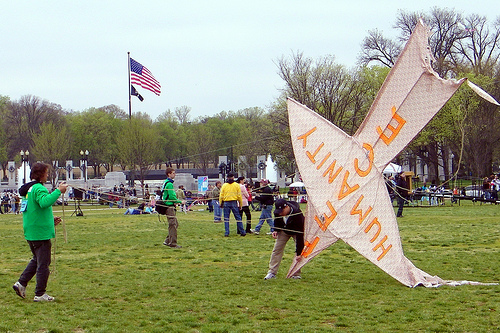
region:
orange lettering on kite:
[298, 125, 404, 267]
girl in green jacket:
[15, 180, 62, 242]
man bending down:
[259, 193, 305, 270]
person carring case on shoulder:
[153, 172, 173, 217]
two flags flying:
[113, 75, 174, 100]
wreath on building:
[254, 150, 265, 177]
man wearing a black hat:
[270, 188, 291, 216]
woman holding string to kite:
[14, 165, 325, 295]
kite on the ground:
[281, 23, 426, 313]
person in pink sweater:
[240, 175, 257, 231]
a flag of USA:
[104, 50, 219, 120]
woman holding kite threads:
[12, 128, 128, 289]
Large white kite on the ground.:
[266, 23, 466, 290]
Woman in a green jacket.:
[15, 155, 62, 305]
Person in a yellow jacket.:
[215, 171, 245, 236]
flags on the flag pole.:
[122, 49, 161, 106]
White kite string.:
[64, 135, 320, 239]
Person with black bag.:
[155, 165, 184, 248]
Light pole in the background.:
[76, 146, 92, 181]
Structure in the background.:
[400, 145, 455, 182]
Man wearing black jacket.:
[263, 197, 305, 282]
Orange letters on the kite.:
[282, 33, 452, 300]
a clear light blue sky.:
[6, 17, 102, 72]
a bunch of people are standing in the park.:
[416, 174, 498, 204]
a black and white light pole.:
[75, 147, 92, 177]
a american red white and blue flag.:
[120, 48, 160, 119]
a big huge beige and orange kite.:
[283, 17, 498, 291]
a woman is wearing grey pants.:
[33, 242, 50, 268]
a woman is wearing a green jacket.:
[28, 209, 46, 222]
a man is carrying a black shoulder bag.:
[153, 177, 178, 214]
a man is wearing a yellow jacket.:
[222, 186, 240, 201]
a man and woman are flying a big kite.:
[8, 1, 498, 306]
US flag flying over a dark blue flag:
[122, 49, 162, 101]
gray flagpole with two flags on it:
[122, 49, 161, 123]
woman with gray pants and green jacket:
[10, 161, 70, 303]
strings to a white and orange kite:
[70, 132, 324, 242]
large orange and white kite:
[282, 17, 494, 306]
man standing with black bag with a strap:
[149, 167, 185, 245]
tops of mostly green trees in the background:
[0, 90, 270, 154]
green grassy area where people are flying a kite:
[65, 285, 497, 329]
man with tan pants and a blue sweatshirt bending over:
[262, 194, 309, 280]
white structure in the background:
[254, 150, 294, 189]